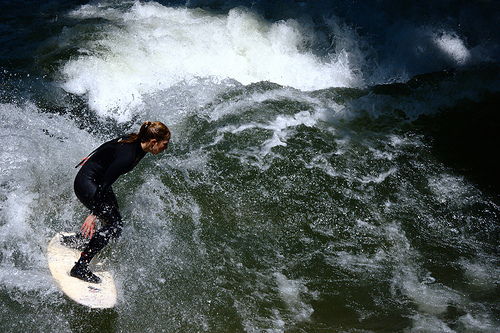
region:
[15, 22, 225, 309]
a woman surfing a wave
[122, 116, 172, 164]
a woman with blonde hair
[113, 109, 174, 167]
a woman with a pony tail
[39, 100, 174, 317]
a woman on a surfboard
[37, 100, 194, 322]
a woman on a white surfboard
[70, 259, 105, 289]
the foot of a woman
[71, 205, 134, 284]
the leg of a woman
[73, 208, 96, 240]
the hand of a woman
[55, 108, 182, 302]
a woman wearing a wetsuit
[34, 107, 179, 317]
a woman wearing a black wetsuit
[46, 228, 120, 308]
A white surfboard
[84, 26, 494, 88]
A lot of white surf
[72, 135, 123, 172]
The zipper string to the girls wet suit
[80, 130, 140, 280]
The girls black wet suit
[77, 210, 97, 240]
The girls bare hands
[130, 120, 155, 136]
The girls pony tail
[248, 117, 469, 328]
The more calm waters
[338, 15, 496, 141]
The very dark shadows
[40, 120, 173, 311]
A girl surfing in the ocean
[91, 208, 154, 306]
The water splashing around the surf board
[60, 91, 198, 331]
woman riding a surf board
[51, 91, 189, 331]
a woman surfing in the water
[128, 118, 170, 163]
a woman with wet hair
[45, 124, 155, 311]
a woman wearing a black wet suit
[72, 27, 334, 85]
a white wave in the ocean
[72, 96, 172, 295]
a woman bent over on a surf board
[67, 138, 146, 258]
a woman with her hand down to her side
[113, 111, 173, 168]
a woman with her hair in a pony tail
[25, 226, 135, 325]
a white surf board in the water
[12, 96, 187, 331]
a woman surfing on a white surf board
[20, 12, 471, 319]
surfing on the wild water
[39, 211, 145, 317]
a white surfboard on the water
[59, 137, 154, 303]
she is wearing a black wet suit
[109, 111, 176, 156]
she is looking at the water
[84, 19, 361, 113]
the waves are agitated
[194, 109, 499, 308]
the water is churning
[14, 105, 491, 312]
a lot of waves in the water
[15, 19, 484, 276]
the water is rugged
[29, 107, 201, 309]
this surfer has good balance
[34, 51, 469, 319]
the surfer is taking on the waves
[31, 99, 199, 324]
a woman riding a surf board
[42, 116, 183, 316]
a woman riding a white surf board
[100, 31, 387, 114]
white waves in the water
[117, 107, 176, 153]
a woman with wet hair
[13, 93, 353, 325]
a woman riding a wave on a surf board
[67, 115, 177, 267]
a woman with her hand out to her side